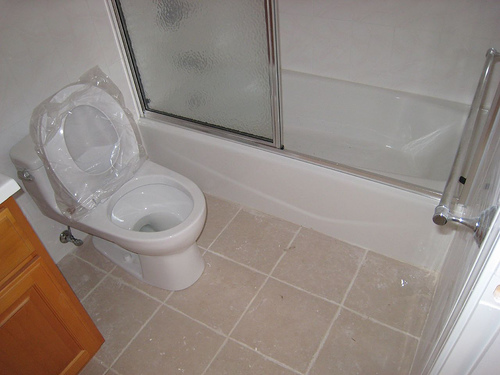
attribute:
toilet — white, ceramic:
[9, 66, 210, 293]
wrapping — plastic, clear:
[30, 65, 150, 223]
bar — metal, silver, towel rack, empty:
[432, 48, 497, 250]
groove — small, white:
[267, 274, 341, 308]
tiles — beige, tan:
[229, 226, 367, 374]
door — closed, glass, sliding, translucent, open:
[109, 2, 284, 151]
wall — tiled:
[416, 120, 499, 374]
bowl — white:
[81, 160, 205, 295]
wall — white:
[1, 1, 138, 265]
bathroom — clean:
[1, 3, 500, 374]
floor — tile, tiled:
[54, 191, 435, 374]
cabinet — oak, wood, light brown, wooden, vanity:
[1, 198, 105, 374]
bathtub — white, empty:
[137, 73, 487, 280]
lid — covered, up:
[42, 85, 142, 208]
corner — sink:
[1, 176, 22, 214]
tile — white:
[275, 0, 500, 112]